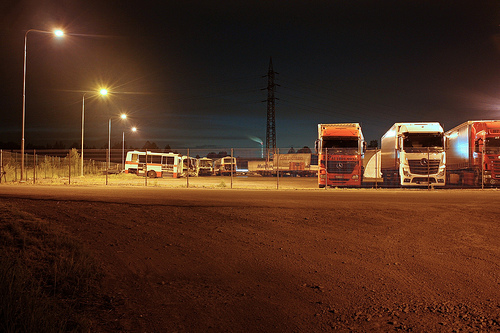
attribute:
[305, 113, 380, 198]
buses — white, orange, grouped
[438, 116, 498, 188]
truck — parked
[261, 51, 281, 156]
power line — tall, distant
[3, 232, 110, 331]
patch — small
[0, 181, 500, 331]
soil — brown, rich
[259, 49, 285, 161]
tower — black, tall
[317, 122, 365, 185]
truck — bright orange, semi truck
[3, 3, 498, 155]
sky — dark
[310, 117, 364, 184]
tractor — white, red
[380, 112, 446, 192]
tractor — white, red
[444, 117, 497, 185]
tractor — white, red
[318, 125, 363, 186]
truck — orange, white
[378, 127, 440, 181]
truck — orange, white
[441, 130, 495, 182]
truck — orange, white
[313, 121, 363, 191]
truck — parked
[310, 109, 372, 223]
truck — parked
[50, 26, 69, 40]
light — bright, lit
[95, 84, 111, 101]
light — bright, lit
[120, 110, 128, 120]
light — bright, lit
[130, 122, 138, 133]
light — bright, lit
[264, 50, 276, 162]
chimney — industrial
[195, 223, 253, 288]
dirt — brown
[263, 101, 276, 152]
pole — metal